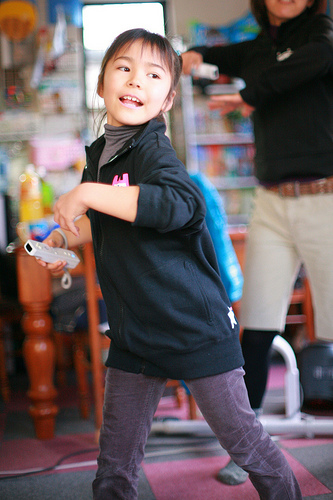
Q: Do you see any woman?
A: Yes, there is a woman.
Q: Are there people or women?
A: Yes, there is a woman.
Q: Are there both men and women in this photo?
A: No, there is a woman but no men.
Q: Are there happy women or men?
A: Yes, there is a happy woman.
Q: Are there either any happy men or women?
A: Yes, there is a happy woman.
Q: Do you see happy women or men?
A: Yes, there is a happy woman.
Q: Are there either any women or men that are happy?
A: Yes, the woman is happy.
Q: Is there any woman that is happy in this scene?
A: Yes, there is a happy woman.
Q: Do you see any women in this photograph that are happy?
A: Yes, there is a woman that is happy.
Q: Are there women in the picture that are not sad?
A: Yes, there is a happy woman.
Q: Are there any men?
A: No, there are no men.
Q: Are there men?
A: No, there are no men.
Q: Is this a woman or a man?
A: This is a woman.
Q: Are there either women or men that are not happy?
A: No, there is a woman but she is happy.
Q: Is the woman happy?
A: Yes, the woman is happy.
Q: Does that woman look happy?
A: Yes, the woman is happy.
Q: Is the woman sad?
A: No, the woman is happy.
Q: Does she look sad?
A: No, the woman is happy.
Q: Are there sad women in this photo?
A: No, there is a woman but she is happy.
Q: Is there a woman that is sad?
A: No, there is a woman but she is happy.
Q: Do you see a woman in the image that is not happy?
A: No, there is a woman but she is happy.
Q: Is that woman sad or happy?
A: The woman is happy.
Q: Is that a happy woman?
A: Yes, that is a happy woman.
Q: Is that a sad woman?
A: No, that is a happy woman.